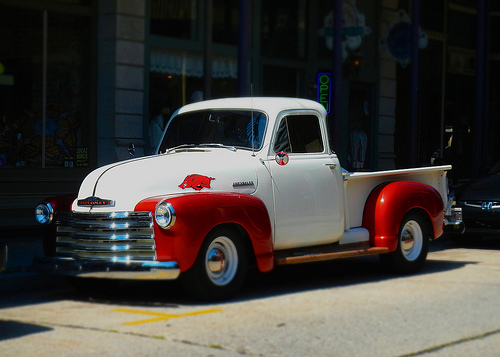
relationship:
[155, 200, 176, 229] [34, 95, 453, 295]
light on truck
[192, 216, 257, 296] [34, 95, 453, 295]
tire on truck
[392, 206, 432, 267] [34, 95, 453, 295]
tire on truck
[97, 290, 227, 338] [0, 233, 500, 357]
guidlines on pavement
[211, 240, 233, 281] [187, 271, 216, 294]
hubcaps against tires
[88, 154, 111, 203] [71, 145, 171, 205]
stripe over middle hood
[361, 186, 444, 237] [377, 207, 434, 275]
metal over tire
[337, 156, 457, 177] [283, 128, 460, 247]
edge on side truck